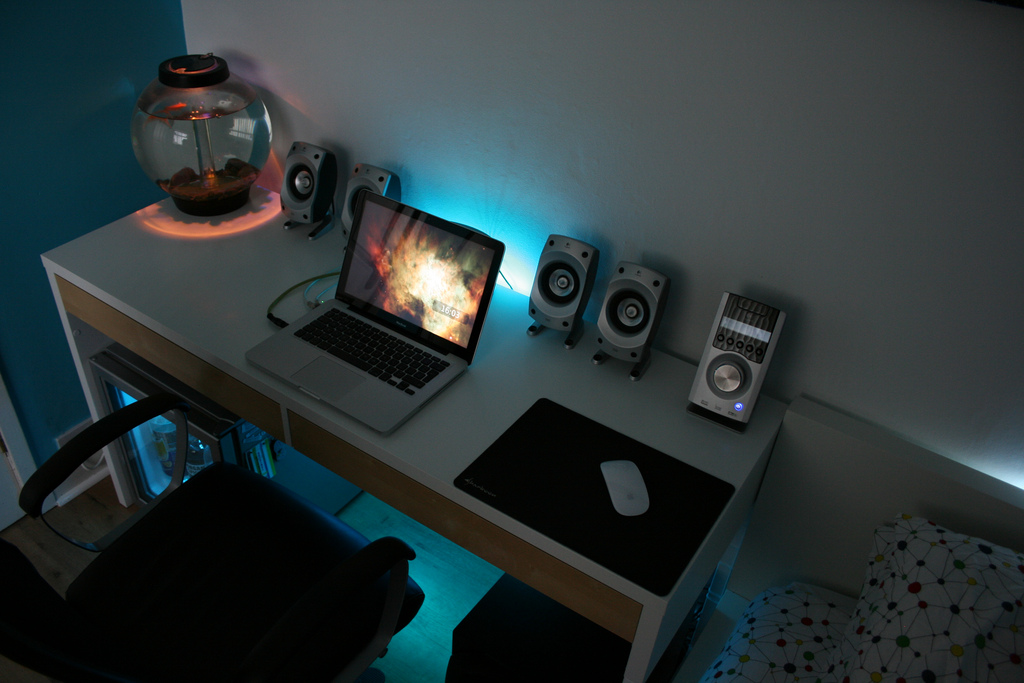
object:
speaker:
[521, 230, 598, 352]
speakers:
[590, 258, 671, 382]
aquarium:
[126, 49, 276, 219]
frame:
[722, 394, 1024, 608]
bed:
[676, 393, 1023, 683]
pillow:
[840, 504, 1024, 683]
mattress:
[711, 571, 854, 681]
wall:
[0, 2, 185, 484]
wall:
[177, 0, 1024, 489]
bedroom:
[0, 0, 1024, 683]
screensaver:
[342, 196, 493, 352]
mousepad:
[447, 398, 738, 596]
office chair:
[2, 345, 426, 683]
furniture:
[819, 520, 1023, 683]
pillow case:
[827, 515, 1024, 683]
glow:
[401, 174, 542, 302]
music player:
[686, 291, 790, 432]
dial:
[704, 356, 752, 399]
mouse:
[597, 459, 653, 520]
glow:
[132, 189, 328, 241]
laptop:
[244, 191, 504, 439]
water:
[128, 95, 272, 219]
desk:
[38, 178, 791, 683]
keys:
[335, 334, 371, 349]